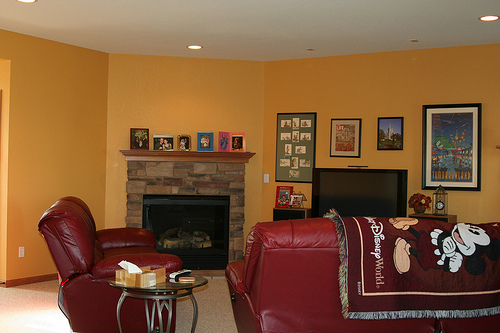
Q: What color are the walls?
A: Yellow.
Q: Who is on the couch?
A: Unoccupied.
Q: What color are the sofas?
A: Red.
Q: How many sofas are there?
A: Two.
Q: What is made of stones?
A: The fireplace.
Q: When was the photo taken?
A: Day time.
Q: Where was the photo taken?
A: In the sitting room.